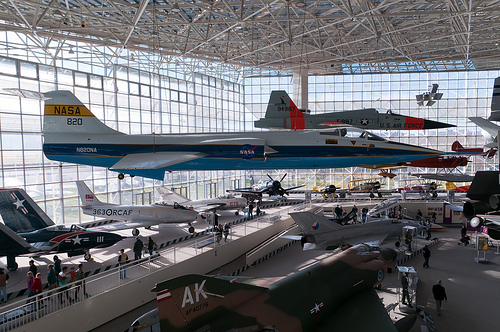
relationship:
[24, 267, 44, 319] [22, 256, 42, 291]
person wearing shirt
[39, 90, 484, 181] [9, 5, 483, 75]
airplane on cieling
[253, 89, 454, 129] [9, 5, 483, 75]
plane on cieling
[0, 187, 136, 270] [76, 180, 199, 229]
jet beside airplane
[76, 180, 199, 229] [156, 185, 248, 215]
airplane beside small plane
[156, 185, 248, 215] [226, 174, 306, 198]
small plane beside small plane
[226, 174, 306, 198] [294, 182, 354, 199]
small plane beside small plane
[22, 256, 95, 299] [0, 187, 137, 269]
people in front of plane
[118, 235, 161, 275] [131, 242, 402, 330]
people in front of plane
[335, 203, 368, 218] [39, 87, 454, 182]
people in front of plane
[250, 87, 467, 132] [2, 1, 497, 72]
airplane hanging from ceiling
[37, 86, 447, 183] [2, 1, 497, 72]
airplane hanging from ceiling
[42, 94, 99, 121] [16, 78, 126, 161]
nasa written on tail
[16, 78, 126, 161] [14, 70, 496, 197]
tail of plane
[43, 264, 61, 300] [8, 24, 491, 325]
people inside museum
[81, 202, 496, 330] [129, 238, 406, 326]
floor with plane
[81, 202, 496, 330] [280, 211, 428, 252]
floor with airplane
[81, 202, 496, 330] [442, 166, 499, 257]
floor with plane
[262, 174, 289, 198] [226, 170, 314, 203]
propeller on plane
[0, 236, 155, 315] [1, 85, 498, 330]
visitors observing planes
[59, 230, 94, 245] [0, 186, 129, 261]
logo painted on a jet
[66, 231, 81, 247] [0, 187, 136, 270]
stars on side of jet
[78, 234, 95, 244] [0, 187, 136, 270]
stripes on side of jet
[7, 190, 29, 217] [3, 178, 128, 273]
logo painted on jet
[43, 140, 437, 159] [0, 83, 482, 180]
stripe painted on plane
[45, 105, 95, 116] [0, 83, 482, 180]
nasa painted on plane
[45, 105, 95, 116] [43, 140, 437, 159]
nasa painted on stripe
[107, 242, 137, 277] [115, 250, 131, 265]
person wearing yellow shirt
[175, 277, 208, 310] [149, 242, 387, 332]
ak on airplane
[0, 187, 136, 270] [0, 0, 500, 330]
jet in showroom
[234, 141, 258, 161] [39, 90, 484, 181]
nasa painted on airplane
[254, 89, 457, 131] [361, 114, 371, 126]
airplane with us logo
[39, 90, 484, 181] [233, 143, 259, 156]
airplane with stars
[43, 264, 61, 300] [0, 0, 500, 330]
people in showroom